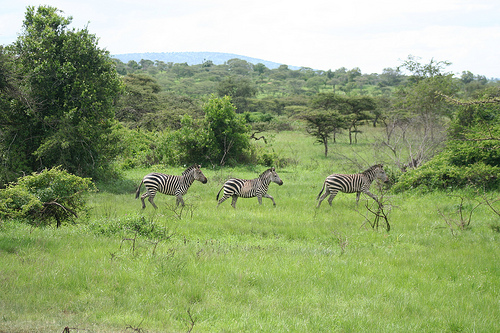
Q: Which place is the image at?
A: It is at the forest.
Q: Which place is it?
A: It is a forest.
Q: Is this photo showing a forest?
A: Yes, it is showing a forest.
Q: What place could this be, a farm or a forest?
A: It is a forest.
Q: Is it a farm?
A: No, it is a forest.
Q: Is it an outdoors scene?
A: Yes, it is outdoors.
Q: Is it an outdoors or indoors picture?
A: It is outdoors.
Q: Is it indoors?
A: No, it is outdoors.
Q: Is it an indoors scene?
A: No, it is outdoors.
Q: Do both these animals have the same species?
A: Yes, all the animals are zebras.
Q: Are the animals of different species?
A: No, all the animals are zebras.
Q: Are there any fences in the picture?
A: No, there are no fences.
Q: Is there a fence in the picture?
A: No, there are no fences.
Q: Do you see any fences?
A: No, there are no fences.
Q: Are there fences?
A: No, there are no fences.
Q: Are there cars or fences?
A: No, there are no fences or cars.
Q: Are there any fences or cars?
A: No, there are no fences or cars.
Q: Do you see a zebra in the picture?
A: Yes, there is a zebra.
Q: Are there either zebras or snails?
A: Yes, there is a zebra.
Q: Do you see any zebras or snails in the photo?
A: Yes, there is a zebra.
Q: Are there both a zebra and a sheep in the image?
A: No, there is a zebra but no sheep.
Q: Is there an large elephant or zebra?
A: Yes, there is a large zebra.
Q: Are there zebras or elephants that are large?
A: Yes, the zebra is large.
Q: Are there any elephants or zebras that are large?
A: Yes, the zebra is large.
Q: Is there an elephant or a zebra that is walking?
A: Yes, the zebra is walking.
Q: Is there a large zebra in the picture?
A: Yes, there is a large zebra.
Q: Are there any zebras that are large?
A: Yes, there is a zebra that is large.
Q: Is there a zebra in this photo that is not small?
A: Yes, there is a large zebra.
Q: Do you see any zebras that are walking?
A: Yes, there is a zebra that is walking.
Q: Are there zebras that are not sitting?
A: Yes, there is a zebra that is walking.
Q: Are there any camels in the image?
A: No, there are no camels.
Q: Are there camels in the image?
A: No, there are no camels.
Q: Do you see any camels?
A: No, there are no camels.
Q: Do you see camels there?
A: No, there are no camels.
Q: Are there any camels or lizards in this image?
A: No, there are no camels or lizards.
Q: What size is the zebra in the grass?
A: The zebra is large.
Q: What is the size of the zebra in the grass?
A: The zebra is large.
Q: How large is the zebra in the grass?
A: The zebra is large.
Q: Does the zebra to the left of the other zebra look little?
A: No, the zebra is large.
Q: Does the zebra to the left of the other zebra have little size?
A: No, the zebra is large.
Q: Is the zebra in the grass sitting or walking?
A: The zebra is walking.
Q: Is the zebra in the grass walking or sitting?
A: The zebra is walking.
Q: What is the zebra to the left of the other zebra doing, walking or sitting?
A: The zebra is walking.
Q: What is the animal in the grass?
A: The animal is a zebra.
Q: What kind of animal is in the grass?
A: The animal is a zebra.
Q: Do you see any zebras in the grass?
A: Yes, there is a zebra in the grass.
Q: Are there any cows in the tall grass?
A: No, there is a zebra in the grass.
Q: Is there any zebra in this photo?
A: Yes, there is a zebra.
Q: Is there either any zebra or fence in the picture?
A: Yes, there is a zebra.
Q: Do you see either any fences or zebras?
A: Yes, there is a zebra.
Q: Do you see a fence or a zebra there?
A: Yes, there is a zebra.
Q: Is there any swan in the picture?
A: No, there are no swans.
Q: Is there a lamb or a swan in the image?
A: No, there are no swans or lambs.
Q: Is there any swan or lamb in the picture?
A: No, there are no swans or lambs.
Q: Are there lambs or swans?
A: No, there are no swans or lambs.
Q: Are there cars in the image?
A: No, there are no cars.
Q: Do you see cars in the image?
A: No, there are no cars.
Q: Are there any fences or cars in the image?
A: No, there are no cars or fences.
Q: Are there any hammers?
A: No, there are no hammers.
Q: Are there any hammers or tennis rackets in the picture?
A: No, there are no hammers or tennis rackets.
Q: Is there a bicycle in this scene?
A: No, there are no bicycles.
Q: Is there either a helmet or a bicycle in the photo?
A: No, there are no bicycles or helmets.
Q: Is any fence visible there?
A: No, there are no fences.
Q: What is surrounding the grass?
A: The forest is surrounding the grass.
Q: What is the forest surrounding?
A: The forest is surrounding the grass.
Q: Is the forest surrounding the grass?
A: Yes, the forest is surrounding the grass.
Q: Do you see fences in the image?
A: No, there are no fences.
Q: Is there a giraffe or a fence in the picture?
A: No, there are no fences or giraffes.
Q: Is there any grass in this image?
A: Yes, there is grass.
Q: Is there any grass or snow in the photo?
A: Yes, there is grass.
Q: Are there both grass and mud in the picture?
A: No, there is grass but no mud.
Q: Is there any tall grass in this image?
A: Yes, there is tall grass.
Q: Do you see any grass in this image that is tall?
A: Yes, there is grass that is tall.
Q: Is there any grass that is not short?
A: Yes, there is tall grass.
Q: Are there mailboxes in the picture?
A: No, there are no mailboxes.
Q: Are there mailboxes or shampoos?
A: No, there are no mailboxes or shampoos.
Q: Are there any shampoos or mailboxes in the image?
A: No, there are no mailboxes or shampoos.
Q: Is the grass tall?
A: Yes, the grass is tall.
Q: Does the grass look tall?
A: Yes, the grass is tall.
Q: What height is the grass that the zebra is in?
A: The grass is tall.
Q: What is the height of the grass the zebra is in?
A: The grass is tall.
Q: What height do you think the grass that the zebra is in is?
A: The grass is tall.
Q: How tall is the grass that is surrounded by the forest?
A: The grass is tall.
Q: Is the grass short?
A: No, the grass is tall.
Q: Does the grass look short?
A: No, the grass is tall.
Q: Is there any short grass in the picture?
A: No, there is grass but it is tall.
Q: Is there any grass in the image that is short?
A: No, there is grass but it is tall.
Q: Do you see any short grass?
A: No, there is grass but it is tall.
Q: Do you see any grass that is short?
A: No, there is grass but it is tall.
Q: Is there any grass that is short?
A: No, there is grass but it is tall.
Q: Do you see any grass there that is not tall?
A: No, there is grass but it is tall.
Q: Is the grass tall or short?
A: The grass is tall.